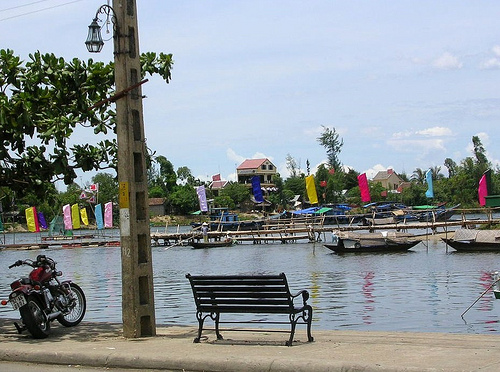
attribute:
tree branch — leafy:
[0, 50, 175, 204]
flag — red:
[353, 170, 370, 201]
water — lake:
[2, 222, 497, 340]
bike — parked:
[2, 255, 86, 339]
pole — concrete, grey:
[103, 1, 160, 336]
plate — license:
[24, 250, 126, 330]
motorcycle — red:
[7, 250, 89, 333]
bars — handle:
[7, 247, 52, 272]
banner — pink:
[474, 170, 491, 203]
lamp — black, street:
[84, 4, 119, 60]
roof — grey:
[362, 141, 421, 188]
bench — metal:
[180, 269, 315, 345]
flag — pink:
[47, 201, 78, 236]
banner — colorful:
[475, 173, 490, 208]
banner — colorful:
[420, 169, 437, 199]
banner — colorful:
[354, 171, 372, 203]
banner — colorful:
[302, 172, 321, 204]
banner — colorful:
[246, 175, 266, 205]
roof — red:
[239, 160, 261, 167]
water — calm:
[1, 213, 497, 329]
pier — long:
[0, 216, 485, 252]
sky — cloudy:
[1, 2, 482, 183]